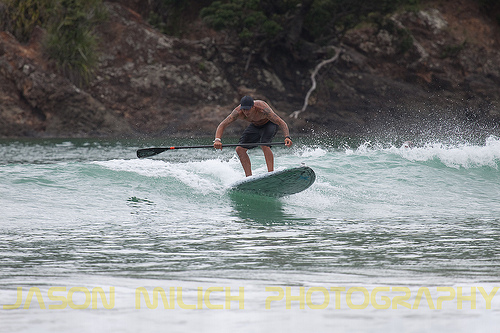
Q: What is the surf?
A: Calm.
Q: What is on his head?
A: A cap.